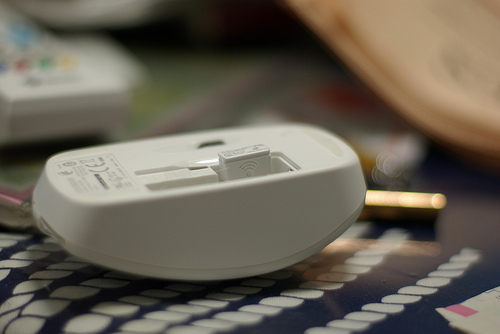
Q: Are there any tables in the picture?
A: Yes, there is a table.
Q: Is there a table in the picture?
A: Yes, there is a table.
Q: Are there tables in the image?
A: Yes, there is a table.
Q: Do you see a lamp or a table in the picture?
A: Yes, there is a table.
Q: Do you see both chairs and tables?
A: No, there is a table but no chairs.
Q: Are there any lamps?
A: No, there are no lamps.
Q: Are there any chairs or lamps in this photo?
A: No, there are no lamps or chairs.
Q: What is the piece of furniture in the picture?
A: The piece of furniture is a table.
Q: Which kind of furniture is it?
A: The piece of furniture is a table.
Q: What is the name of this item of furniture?
A: That is a table.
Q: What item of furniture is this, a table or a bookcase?
A: That is a table.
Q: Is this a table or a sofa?
A: This is a table.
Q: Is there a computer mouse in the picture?
A: Yes, there is a computer mouse.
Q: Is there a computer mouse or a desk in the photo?
A: Yes, there is a computer mouse.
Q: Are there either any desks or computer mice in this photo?
A: Yes, there is a computer mouse.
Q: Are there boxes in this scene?
A: No, there are no boxes.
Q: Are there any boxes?
A: No, there are no boxes.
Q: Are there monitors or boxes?
A: No, there are no boxes or monitors.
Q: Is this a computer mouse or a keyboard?
A: This is a computer mouse.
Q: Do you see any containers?
A: No, there are no containers.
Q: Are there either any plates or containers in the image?
A: No, there are no containers or plates.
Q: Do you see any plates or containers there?
A: No, there are no containers or plates.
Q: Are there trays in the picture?
A: No, there are no trays.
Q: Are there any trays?
A: No, there are no trays.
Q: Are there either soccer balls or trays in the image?
A: No, there are no trays or soccer balls.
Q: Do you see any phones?
A: Yes, there is a phone.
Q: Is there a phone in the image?
A: Yes, there is a phone.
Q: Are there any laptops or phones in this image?
A: Yes, there is a phone.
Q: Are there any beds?
A: No, there are no beds.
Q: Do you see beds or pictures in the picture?
A: No, there are no beds or pictures.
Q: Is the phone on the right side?
A: No, the phone is on the left of the image.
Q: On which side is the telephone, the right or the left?
A: The telephone is on the left of the image.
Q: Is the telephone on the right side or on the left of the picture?
A: The telephone is on the left of the image.